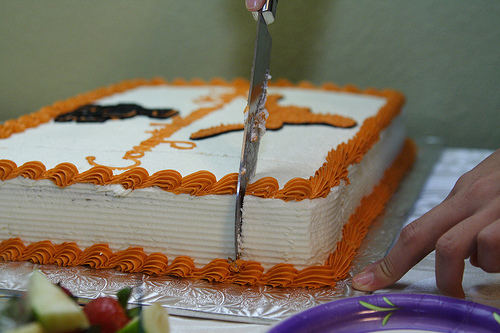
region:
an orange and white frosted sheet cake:
[5, 61, 410, 285]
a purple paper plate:
[258, 279, 499, 331]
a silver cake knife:
[220, 0, 285, 259]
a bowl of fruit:
[10, 274, 167, 330]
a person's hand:
[350, 146, 495, 311]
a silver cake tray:
[0, 116, 442, 322]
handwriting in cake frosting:
[90, 79, 256, 173]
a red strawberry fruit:
[78, 296, 123, 331]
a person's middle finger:
[348, 188, 471, 294]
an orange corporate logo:
[190, 88, 358, 145]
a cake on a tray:
[12, 47, 425, 278]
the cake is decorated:
[1, 44, 418, 284]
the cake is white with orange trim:
[1, 76, 416, 298]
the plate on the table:
[261, 291, 493, 331]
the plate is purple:
[233, 290, 488, 331]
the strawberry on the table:
[76, 276, 152, 318]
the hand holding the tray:
[336, 142, 498, 292]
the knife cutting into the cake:
[223, 5, 278, 277]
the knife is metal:
[219, 8, 281, 265]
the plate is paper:
[255, 280, 452, 331]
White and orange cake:
[16, 53, 398, 288]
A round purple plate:
[264, 275, 486, 327]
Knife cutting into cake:
[204, 13, 288, 265]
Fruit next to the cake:
[26, 258, 127, 322]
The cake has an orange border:
[8, 38, 425, 302]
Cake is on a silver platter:
[8, 121, 460, 311]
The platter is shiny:
[3, 138, 449, 320]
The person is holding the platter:
[318, 148, 490, 290]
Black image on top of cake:
[62, 83, 179, 145]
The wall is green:
[37, 11, 451, 119]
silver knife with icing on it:
[235, 6, 286, 253]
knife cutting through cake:
[215, 13, 292, 266]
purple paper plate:
[300, 283, 496, 329]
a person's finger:
[350, 195, 498, 275]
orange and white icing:
[296, 86, 416, 291]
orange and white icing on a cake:
[0, 79, 399, 294]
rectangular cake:
[0, 77, 403, 282]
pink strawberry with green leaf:
[76, 286, 153, 331]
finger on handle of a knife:
[246, 0, 269, 22]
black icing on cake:
[50, 86, 179, 132]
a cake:
[14, 23, 214, 330]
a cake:
[124, 94, 254, 313]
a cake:
[92, 123, 206, 323]